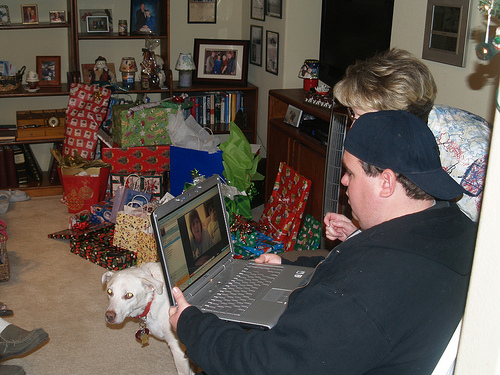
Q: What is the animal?
A: Dog.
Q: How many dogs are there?
A: 1.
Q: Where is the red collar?
A: Dog's neck.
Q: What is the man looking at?
A: Laptop.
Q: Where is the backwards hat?
A: Man's head.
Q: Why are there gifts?
A: It's Christmas.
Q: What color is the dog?
A: White.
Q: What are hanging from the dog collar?
A: Tags.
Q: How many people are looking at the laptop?
A: 2.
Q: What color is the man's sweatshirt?
A: Black.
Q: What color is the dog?
A: White.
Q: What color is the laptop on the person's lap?
A: Silver.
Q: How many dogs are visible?
A: One.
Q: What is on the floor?
A: Holiday presents.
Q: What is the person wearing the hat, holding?
A: A laptop.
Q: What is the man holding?
A: A laptop.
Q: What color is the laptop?
A: Grey.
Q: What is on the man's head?
A: A black hat.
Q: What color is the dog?
A: White.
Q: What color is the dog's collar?
A: Red.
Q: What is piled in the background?
A: Gifts.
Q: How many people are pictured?
A: Two.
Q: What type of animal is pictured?
A: Dog.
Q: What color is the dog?
A: White.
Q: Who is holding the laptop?
A: The man.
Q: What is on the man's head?
A: A hat.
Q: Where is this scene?
A: The living room.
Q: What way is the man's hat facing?
A: Backwards.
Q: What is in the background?
A: Presents.